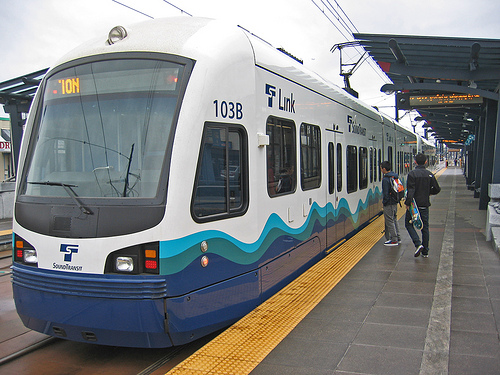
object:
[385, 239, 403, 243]
shoes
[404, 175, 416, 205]
arm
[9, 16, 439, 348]
train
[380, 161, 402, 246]
boy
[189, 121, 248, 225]
window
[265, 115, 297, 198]
window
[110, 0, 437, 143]
utility lines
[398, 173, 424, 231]
skateboard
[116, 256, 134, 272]
headlight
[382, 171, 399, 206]
jacket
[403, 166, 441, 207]
jacket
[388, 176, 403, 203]
backpack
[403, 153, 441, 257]
boy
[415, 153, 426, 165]
hair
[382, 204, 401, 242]
leg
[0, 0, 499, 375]
station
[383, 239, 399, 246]
shoes